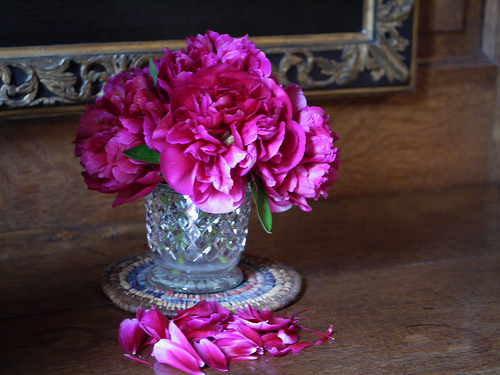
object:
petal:
[119, 318, 142, 355]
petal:
[198, 338, 228, 371]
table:
[1, 66, 500, 374]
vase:
[145, 180, 253, 294]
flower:
[73, 97, 165, 209]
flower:
[262, 105, 340, 212]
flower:
[172, 63, 260, 131]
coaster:
[100, 251, 303, 319]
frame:
[0, 0, 421, 122]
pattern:
[1, 60, 81, 105]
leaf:
[122, 143, 163, 164]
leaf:
[251, 172, 273, 235]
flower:
[98, 57, 166, 121]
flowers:
[159, 111, 261, 214]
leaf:
[149, 54, 159, 86]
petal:
[233, 314, 291, 333]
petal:
[154, 338, 206, 375]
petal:
[139, 307, 169, 341]